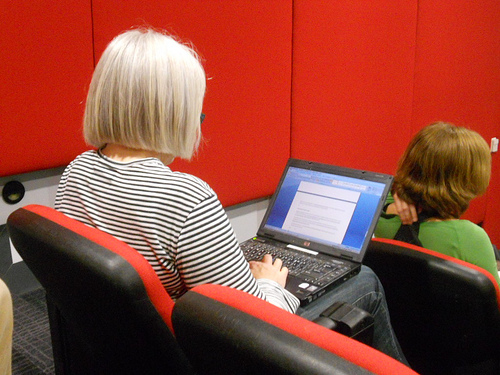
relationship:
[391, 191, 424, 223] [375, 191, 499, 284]
hand scratching back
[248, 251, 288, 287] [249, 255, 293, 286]
hand operating trackpad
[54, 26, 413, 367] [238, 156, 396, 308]
woman holding laptop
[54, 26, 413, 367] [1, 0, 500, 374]
woman in room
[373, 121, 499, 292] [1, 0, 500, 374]
woman in room